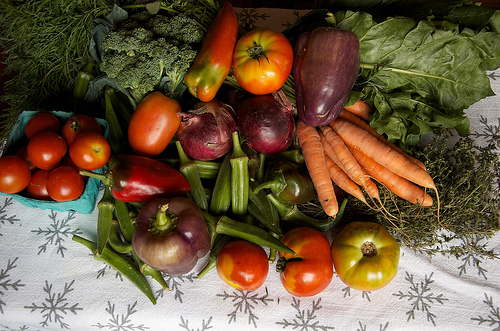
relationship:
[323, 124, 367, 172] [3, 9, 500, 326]
carrot on table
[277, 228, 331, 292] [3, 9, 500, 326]
tomatoe on table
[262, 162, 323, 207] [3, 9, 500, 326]
pepper on table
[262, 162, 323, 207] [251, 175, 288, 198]
pepper has stem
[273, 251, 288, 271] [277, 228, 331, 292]
stem of tomatoe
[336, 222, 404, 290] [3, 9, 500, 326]
tomatoe on table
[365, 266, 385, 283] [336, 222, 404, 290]
light on tomatoe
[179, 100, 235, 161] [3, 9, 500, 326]
onion on table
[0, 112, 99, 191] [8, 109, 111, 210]
tomatoes in carton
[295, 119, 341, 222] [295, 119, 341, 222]
carrot in carrot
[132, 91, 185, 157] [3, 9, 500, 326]
tomatoe on table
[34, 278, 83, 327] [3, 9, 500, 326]
snowflake on table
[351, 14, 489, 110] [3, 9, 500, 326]
spinach on table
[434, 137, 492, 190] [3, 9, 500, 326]
parsley on table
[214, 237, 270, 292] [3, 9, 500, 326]
tomatoe on table